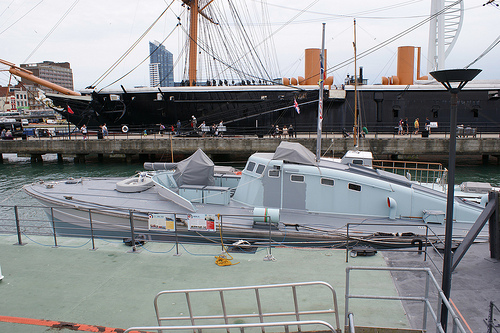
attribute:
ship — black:
[43, 75, 491, 148]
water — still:
[1, 155, 76, 227]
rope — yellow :
[215, 216, 240, 267]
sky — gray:
[4, 7, 119, 49]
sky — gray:
[279, 3, 357, 23]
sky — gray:
[385, 2, 426, 33]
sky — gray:
[473, 11, 499, 33]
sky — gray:
[79, 53, 104, 72]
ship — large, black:
[1, 2, 499, 133]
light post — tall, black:
[427, 60, 489, 332]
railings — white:
[166, 256, 270, 331]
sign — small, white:
[144, 208, 177, 232]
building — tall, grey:
[19, 64, 69, 97]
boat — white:
[30, 131, 485, 252]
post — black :
[438, 90, 460, 331]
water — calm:
[0, 153, 499, 238]